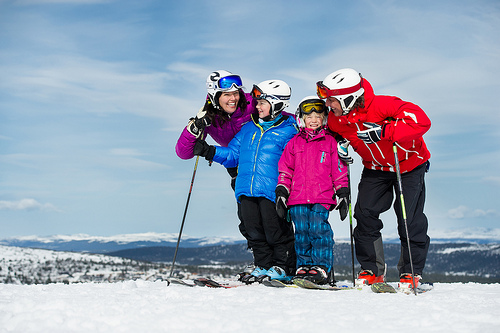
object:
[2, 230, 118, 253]
mountain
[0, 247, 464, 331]
top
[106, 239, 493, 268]
mountain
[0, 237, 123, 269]
snow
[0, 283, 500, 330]
snow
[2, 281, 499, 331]
ground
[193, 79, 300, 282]
boy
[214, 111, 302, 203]
blue jacket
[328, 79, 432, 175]
jacket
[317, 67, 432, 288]
adult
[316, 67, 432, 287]
ski gear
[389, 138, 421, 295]
pole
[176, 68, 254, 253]
female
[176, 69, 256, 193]
ski gear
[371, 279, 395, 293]
skis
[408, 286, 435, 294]
skis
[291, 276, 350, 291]
skis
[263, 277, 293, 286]
skis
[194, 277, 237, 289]
skis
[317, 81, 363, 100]
goggles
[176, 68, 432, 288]
family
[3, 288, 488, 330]
footprints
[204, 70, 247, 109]
helmets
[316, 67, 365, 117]
head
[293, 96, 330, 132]
head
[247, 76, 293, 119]
head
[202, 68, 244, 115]
head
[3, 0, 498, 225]
clouds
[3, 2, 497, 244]
sky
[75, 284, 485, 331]
tracks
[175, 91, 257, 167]
jacket